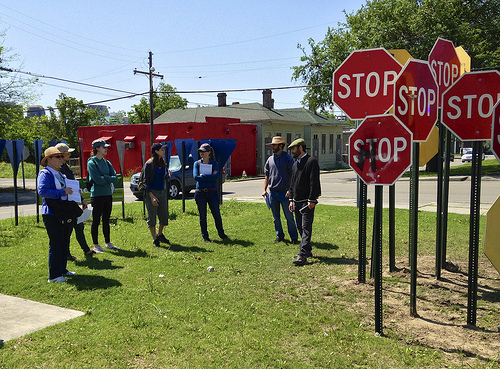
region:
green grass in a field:
[147, 277, 236, 349]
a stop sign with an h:
[347, 115, 412, 187]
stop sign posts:
[352, 185, 474, 308]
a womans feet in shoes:
[45, 267, 80, 292]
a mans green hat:
[286, 133, 308, 150]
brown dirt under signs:
[396, 306, 459, 353]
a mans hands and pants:
[287, 192, 319, 258]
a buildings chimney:
[250, 81, 278, 111]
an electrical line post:
[142, 75, 164, 137]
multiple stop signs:
[325, 75, 495, 167]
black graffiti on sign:
[355, 135, 376, 172]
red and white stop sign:
[345, 111, 410, 181]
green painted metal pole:
[370, 185, 385, 335]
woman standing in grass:
[190, 140, 230, 245]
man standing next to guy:
[260, 135, 295, 245]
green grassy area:
[0, 200, 491, 365]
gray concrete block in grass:
[0, 287, 85, 342]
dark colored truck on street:
[127, 151, 223, 198]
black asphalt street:
[0, 151, 495, 206]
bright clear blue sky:
[0, 0, 366, 115]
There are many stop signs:
[299, 49, 499, 197]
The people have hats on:
[35, 131, 346, 181]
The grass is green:
[135, 250, 289, 315]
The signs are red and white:
[328, 56, 460, 138]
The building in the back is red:
[58, 97, 305, 236]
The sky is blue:
[72, 49, 292, 83]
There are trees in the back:
[6, 87, 222, 152]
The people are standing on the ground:
[32, 199, 386, 349]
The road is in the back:
[207, 155, 492, 238]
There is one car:
[105, 130, 292, 239]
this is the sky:
[121, 4, 196, 32]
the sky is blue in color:
[142, 14, 179, 31]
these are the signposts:
[338, 43, 498, 255]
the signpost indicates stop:
[338, 69, 393, 101]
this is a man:
[41, 147, 75, 274]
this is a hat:
[46, 147, 56, 152]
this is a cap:
[153, 141, 161, 146]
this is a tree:
[358, 8, 430, 43]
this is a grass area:
[146, 272, 243, 352]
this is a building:
[258, 105, 299, 129]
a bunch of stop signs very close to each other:
[330, 24, 499, 271]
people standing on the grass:
[36, 114, 329, 297]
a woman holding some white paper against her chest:
[188, 132, 246, 256]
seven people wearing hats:
[28, 126, 328, 174]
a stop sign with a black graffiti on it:
[347, 117, 415, 187]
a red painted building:
[81, 107, 259, 167]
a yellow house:
[261, 95, 360, 168]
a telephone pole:
[133, 40, 179, 137]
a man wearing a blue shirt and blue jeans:
[258, 135, 291, 236]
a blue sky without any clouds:
[23, 3, 320, 43]